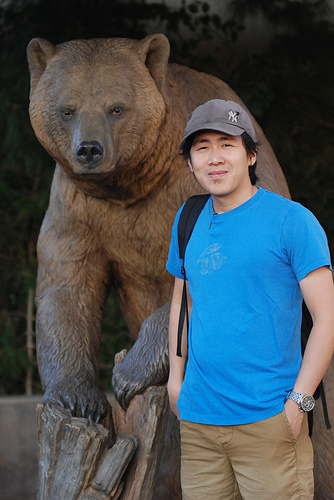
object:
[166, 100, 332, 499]
man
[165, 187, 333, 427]
shirt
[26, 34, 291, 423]
bear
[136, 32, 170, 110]
right ear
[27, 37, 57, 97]
left ear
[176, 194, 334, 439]
backpack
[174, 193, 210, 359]
strap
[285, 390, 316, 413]
watch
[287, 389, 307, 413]
right wrist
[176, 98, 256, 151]
hat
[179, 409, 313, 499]
pants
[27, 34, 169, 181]
head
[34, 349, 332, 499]
log base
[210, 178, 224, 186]
facial hair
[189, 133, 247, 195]
face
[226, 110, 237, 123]
logo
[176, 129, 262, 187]
hair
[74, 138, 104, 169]
nose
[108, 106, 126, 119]
right eye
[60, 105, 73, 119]
left eye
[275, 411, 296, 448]
pocket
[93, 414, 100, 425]
claws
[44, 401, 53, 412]
paw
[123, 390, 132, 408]
paw